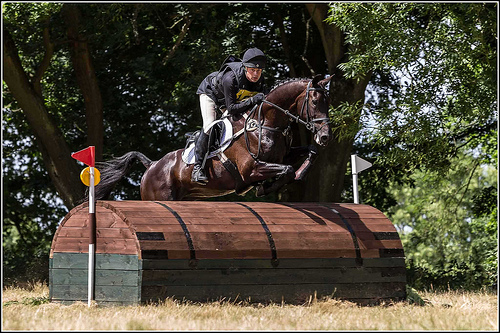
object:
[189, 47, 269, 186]
jockey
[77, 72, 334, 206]
horse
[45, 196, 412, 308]
obstacle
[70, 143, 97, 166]
flag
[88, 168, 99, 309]
post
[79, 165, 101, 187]
circle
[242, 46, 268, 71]
hat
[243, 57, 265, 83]
head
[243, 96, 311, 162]
bridle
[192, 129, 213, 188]
boots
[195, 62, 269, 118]
shirt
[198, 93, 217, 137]
pants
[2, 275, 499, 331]
grass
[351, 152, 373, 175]
flag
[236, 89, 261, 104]
number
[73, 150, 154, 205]
tail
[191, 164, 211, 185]
foot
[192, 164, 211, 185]
stirrup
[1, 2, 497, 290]
leaves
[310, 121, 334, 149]
nose